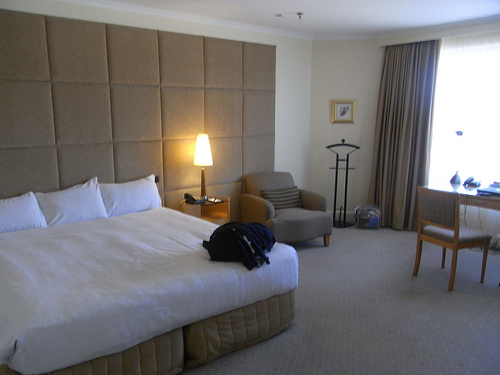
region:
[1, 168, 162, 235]
three white pillows on a bed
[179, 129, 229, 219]
bedside table with lamp, phone other item on top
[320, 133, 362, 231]
black metal clothes stand in front of white wall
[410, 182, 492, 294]
fabric seat and back wooden chair on carpet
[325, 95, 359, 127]
gold framed picture hanging on a white wall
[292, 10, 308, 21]
water sprinkler unit on white ceiling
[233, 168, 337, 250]
brown lounge chair with pillow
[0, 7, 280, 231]
brown fabric texture wall panels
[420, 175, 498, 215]
desk with computer and phone on top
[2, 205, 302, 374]
white bed covering with tan bedskirt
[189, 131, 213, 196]
the lit up lamp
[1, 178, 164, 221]
the three pillows on the bed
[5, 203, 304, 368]
the bed in the room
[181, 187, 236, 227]
the nightstand next to the bed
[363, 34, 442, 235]
the curtains hanging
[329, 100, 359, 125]
the picture hanging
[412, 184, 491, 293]
the wooden chair at the desk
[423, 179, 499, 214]
the desk near the window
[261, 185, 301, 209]
the pillow on the chair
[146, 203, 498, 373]
the carpet on the ground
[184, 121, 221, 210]
Lamp on a table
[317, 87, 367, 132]
Picture on a wall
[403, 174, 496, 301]
Chair on a floor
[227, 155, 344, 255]
Chair in a room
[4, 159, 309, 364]
King sized bed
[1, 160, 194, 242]
Three pillows on bed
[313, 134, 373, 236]
Coat rack in a room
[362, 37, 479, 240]
Curtains on a window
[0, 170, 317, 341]
Covers on a bed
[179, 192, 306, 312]
Clothing on a bed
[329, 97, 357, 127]
a gold picture frame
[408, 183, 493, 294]
a brown and gray chair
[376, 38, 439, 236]
a large brown curtain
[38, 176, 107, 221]
a large white pillow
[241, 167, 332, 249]
a brown chair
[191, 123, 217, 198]
a long brown and white table lamp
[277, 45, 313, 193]
a long white wall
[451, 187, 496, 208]
part of a brown table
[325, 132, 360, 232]
a tall black rack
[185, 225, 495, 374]
gray carpet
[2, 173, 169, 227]
three white pillows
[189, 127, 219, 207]
a table lamp turned on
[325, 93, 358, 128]
square wood picture frame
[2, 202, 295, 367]
a white blanket tucked in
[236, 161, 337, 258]
a grey chair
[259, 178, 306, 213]
a rectangle throw pillow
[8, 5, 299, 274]
grey padded wall behind the bed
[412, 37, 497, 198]
sun shining threw the window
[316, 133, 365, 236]
a metal dress rack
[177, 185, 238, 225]
phone sitting on round table